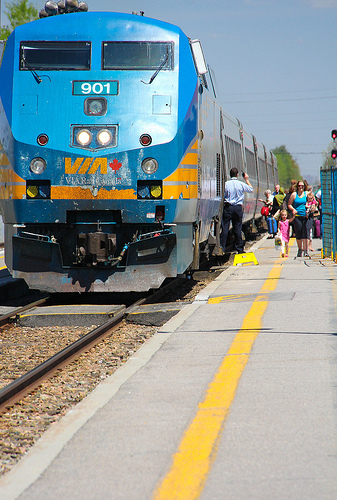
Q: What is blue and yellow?
A: Train.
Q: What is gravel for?
A: Tracks.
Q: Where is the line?
A: Foot path.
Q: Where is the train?
A: On train tracks.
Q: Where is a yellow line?
A: On the ground.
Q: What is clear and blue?
A: Sky.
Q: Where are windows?
A: On the train.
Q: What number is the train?
A: 901.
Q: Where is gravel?
A: On the ground.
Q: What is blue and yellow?
A: Train.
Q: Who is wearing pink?
A: Little girl.